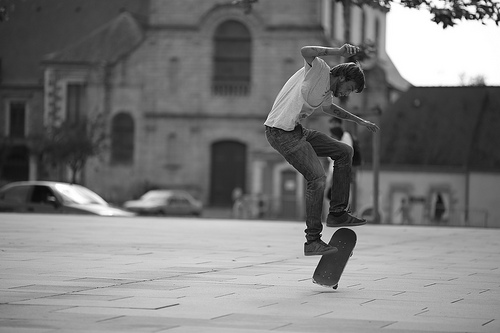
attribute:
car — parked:
[1, 180, 138, 217]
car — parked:
[123, 189, 204, 219]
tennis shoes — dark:
[302, 205, 368, 254]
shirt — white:
[261, 51, 338, 138]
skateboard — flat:
[312, 228, 354, 289]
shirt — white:
[245, 21, 404, 198]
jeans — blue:
[259, 117, 355, 241]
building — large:
[0, 2, 497, 231]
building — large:
[5, 0, 385, 210]